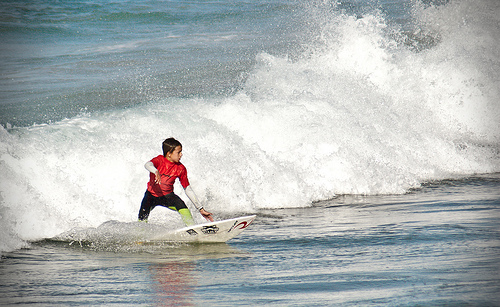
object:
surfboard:
[144, 208, 256, 246]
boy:
[136, 136, 217, 229]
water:
[48, 221, 202, 256]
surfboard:
[152, 211, 256, 245]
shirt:
[145, 155, 204, 210]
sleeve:
[183, 183, 201, 214]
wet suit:
[137, 156, 203, 227]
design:
[185, 221, 249, 237]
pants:
[137, 190, 193, 227]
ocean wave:
[275, 10, 496, 174]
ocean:
[2, 2, 497, 302]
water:
[246, 139, 497, 305]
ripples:
[266, 216, 477, 272]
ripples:
[288, 201, 469, 244]